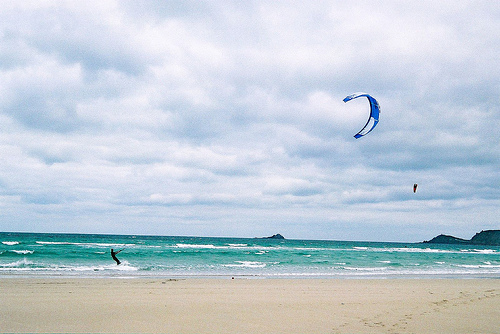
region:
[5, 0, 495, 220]
The sky is cloudy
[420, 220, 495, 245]
Mountains are in the background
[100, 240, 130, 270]
Person is in the background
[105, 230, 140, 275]
The person is in water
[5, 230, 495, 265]
The water is teal colored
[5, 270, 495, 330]
Sand is on the foreground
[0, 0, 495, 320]
Photo was taken in the daytime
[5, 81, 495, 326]
Photo was taken outdoors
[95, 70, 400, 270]
Person is water gliding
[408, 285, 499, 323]
Tracks are in the sand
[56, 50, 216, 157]
white clouds in the sky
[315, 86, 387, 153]
object in the air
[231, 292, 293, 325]
sand below the sky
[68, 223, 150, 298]
person in the water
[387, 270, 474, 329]
tracks in the sand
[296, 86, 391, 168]
blue and white object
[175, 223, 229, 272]
white wave in water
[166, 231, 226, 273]
blue ocean below sky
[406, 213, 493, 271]
hills in the background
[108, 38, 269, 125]
many clouds above water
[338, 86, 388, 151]
a blue kite in the sky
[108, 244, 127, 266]
a man in the water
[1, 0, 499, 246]
a cloudy gray sky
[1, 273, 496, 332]
a sandy brown beach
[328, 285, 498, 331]
tracks in the sand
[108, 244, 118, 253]
the head of a man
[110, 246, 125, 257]
the arms of a man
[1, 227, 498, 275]
blue and white water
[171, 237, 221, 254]
a small white wave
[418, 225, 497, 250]
cliffs in the distance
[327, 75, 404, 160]
Blue and white parasail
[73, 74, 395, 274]
The person is parasailing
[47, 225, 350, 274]
The water is bright blue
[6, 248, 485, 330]
The beach is sandy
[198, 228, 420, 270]
Waves are crashing onto the shore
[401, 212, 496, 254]
Mountains at the waters edge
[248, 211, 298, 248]
Blue island in the water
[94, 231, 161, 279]
Person is wearing black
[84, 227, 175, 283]
Person is holding onto the handle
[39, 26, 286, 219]
The sky is cloudy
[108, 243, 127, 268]
A man kite surfing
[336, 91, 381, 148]
A blue and white kite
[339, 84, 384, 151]
A kite in the air.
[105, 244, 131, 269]
The person is wearing black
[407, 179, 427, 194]
Another kite in the distance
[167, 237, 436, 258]
Waves in the water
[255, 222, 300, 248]
An island in the ocean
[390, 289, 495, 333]
Tracks on the sand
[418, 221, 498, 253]
Hills in the water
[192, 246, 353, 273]
The water is green